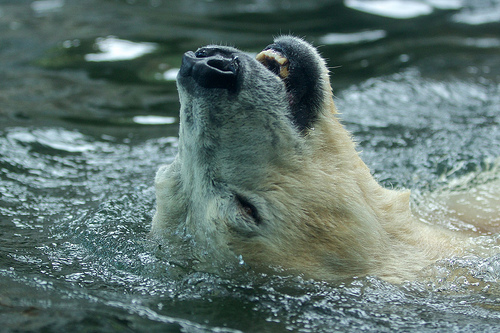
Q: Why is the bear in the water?
A: The bear is swimming.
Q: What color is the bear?
A: White.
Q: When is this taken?
A: Daytime.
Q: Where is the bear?
A: In the water.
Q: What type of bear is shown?
A: A polar bear.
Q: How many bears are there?
A: One.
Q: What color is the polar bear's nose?
A: Black.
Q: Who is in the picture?
A: No one is in the picture.